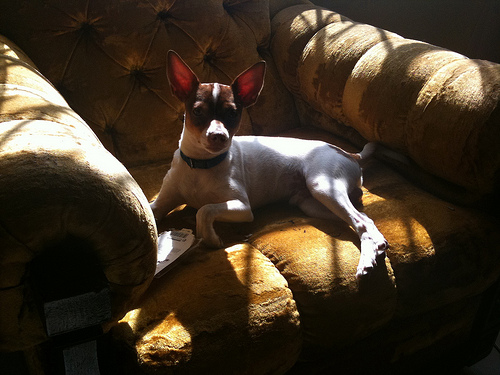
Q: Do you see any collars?
A: Yes, there is a collar.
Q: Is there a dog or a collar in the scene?
A: Yes, there is a collar.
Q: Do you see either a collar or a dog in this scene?
A: Yes, there is a collar.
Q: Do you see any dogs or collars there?
A: Yes, there is a collar.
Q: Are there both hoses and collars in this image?
A: No, there is a collar but no hoses.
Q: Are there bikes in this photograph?
A: No, there are no bikes.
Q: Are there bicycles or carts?
A: No, there are no bicycles or carts.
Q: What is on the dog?
A: The collar is on the dog.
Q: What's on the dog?
A: The collar is on the dog.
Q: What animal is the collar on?
A: The collar is on the dog.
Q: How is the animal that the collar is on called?
A: The animal is a dog.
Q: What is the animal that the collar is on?
A: The animal is a dog.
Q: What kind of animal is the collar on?
A: The collar is on the dog.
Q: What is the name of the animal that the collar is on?
A: The animal is a dog.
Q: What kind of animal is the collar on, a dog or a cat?
A: The collar is on a dog.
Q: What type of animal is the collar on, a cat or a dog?
A: The collar is on a dog.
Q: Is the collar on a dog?
A: Yes, the collar is on a dog.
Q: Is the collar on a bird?
A: No, the collar is on a dog.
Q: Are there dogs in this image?
A: Yes, there is a dog.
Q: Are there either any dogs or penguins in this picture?
A: Yes, there is a dog.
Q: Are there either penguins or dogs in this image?
A: Yes, there is a dog.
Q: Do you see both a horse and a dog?
A: No, there is a dog but no horses.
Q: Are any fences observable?
A: No, there are no fences.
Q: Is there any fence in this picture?
A: No, there are no fences.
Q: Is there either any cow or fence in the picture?
A: No, there are no fences or cows.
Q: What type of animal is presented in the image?
A: The animal is a dog.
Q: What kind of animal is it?
A: The animal is a dog.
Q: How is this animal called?
A: This is a dog.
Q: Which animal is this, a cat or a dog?
A: This is a dog.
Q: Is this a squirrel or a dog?
A: This is a dog.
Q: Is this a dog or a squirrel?
A: This is a dog.